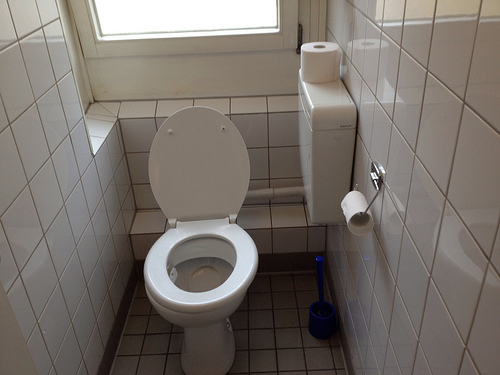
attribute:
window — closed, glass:
[84, 0, 277, 41]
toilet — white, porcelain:
[142, 106, 259, 372]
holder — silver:
[351, 160, 383, 215]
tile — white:
[411, 69, 465, 199]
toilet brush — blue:
[301, 248, 345, 345]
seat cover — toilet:
[147, 107, 249, 227]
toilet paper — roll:
[329, 159, 391, 256]